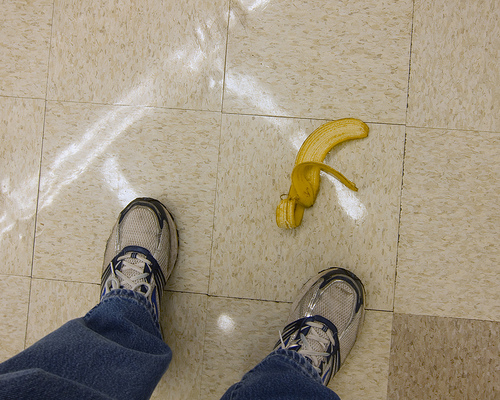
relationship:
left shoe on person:
[99, 195, 181, 338] [0, 291, 342, 398]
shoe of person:
[267, 268, 365, 385] [0, 195, 367, 398]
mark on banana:
[304, 186, 311, 206] [247, 112, 387, 241]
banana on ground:
[247, 112, 387, 241] [204, 61, 497, 274]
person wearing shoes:
[0, 195, 367, 398] [97, 197, 366, 387]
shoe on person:
[267, 268, 365, 385] [78, 186, 375, 398]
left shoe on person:
[99, 195, 181, 338] [78, 186, 375, 398]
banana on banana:
[247, 112, 387, 241] [247, 112, 387, 241]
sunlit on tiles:
[27, 33, 287, 188] [3, 2, 493, 398]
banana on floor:
[247, 112, 387, 241] [7, 6, 487, 388]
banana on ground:
[247, 112, 387, 241] [25, 38, 495, 313]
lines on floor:
[390, 0, 411, 315] [7, 6, 487, 388]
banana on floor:
[247, 112, 387, 241] [58, 35, 490, 292]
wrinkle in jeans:
[84, 309, 172, 362] [0, 286, 339, 398]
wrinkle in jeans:
[0, 367, 117, 398] [0, 286, 339, 398]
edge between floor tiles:
[395, 115, 402, 320] [227, 112, 404, 313]